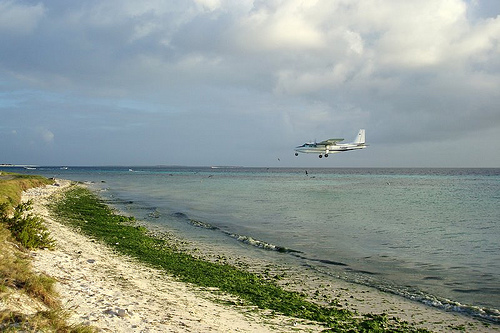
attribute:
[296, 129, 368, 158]
plane — small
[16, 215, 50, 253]
bussh — green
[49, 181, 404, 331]
seaweed — washed, green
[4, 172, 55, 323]
land — grassy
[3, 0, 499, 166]
sky — blue, cloudy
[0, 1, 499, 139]
clouds — white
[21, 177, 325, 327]
sand — white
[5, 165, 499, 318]
ocean — open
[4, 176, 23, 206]
grass — dead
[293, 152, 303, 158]
wheel — black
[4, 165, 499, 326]
sea — blue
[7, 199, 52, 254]
bush — green